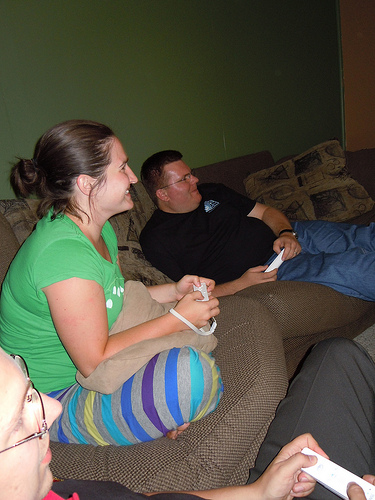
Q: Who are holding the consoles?
A: People.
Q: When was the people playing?
A: Now.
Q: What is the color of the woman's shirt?
A: Green.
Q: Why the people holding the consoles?
A: To play.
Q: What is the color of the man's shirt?
A: Black.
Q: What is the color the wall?
A: Green.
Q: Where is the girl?
A: On the couch.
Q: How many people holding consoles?
A: Three.